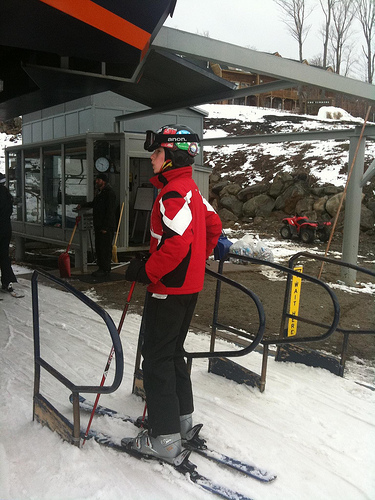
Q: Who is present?
A: A man.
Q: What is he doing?
A: Standing.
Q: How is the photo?
A: Clear.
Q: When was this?
A: Daytime.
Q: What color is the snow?
A: White.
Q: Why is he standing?
A: To ski.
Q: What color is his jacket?
A: Red.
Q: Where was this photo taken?
A: On the snow.